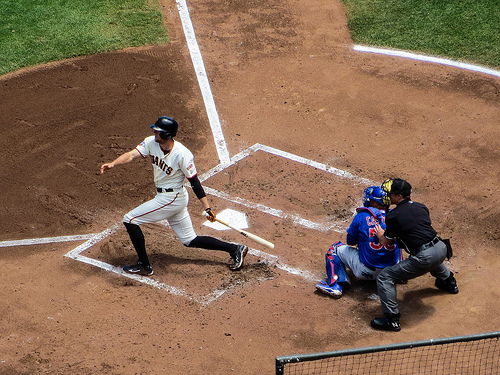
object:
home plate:
[202, 208, 250, 232]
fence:
[271, 331, 500, 375]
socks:
[122, 221, 151, 269]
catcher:
[314, 184, 408, 300]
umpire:
[369, 177, 459, 333]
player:
[99, 115, 250, 277]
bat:
[201, 210, 275, 250]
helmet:
[149, 116, 180, 140]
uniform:
[134, 135, 199, 190]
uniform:
[345, 207, 401, 270]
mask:
[360, 186, 370, 208]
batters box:
[183, 142, 380, 238]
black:
[399, 206, 426, 234]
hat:
[380, 177, 412, 197]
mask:
[379, 185, 391, 210]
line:
[171, 0, 235, 163]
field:
[0, 0, 497, 375]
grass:
[1, 0, 169, 76]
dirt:
[227, 21, 383, 135]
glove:
[203, 206, 216, 223]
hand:
[100, 162, 115, 174]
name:
[149, 155, 174, 176]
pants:
[123, 185, 199, 246]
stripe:
[129, 192, 180, 224]